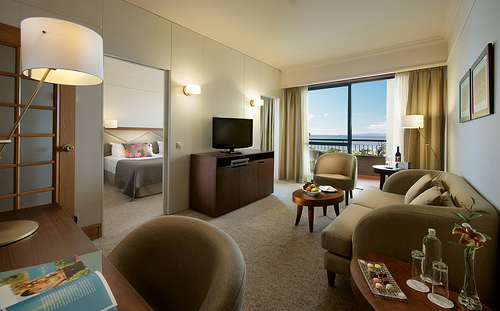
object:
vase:
[456, 245, 481, 310]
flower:
[450, 221, 486, 248]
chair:
[311, 152, 355, 208]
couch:
[319, 169, 497, 307]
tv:
[211, 117, 251, 156]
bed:
[103, 127, 163, 202]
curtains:
[279, 84, 309, 185]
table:
[346, 254, 488, 309]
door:
[1, 23, 75, 222]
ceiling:
[125, 2, 465, 71]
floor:
[101, 183, 322, 309]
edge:
[221, 255, 248, 308]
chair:
[106, 214, 246, 310]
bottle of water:
[419, 228, 443, 281]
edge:
[43, 201, 158, 310]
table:
[0, 200, 152, 309]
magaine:
[0, 250, 116, 308]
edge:
[210, 117, 219, 149]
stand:
[187, 150, 276, 218]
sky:
[308, 85, 385, 137]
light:
[181, 81, 204, 98]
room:
[102, 57, 169, 233]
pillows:
[403, 185, 445, 207]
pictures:
[467, 43, 492, 122]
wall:
[443, 1, 498, 210]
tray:
[354, 256, 408, 300]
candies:
[371, 280, 385, 290]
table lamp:
[0, 16, 106, 247]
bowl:
[301, 183, 319, 196]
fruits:
[309, 188, 317, 193]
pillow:
[119, 142, 151, 159]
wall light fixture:
[250, 99, 261, 108]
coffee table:
[291, 184, 345, 233]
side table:
[370, 164, 402, 190]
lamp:
[399, 113, 423, 130]